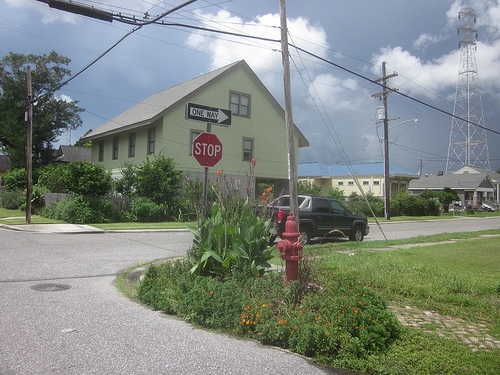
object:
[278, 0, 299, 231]
pole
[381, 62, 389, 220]
pole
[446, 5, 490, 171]
pylon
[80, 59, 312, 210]
house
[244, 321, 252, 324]
flowers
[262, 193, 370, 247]
car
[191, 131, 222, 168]
stop sign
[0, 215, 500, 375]
road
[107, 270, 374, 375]
roadside